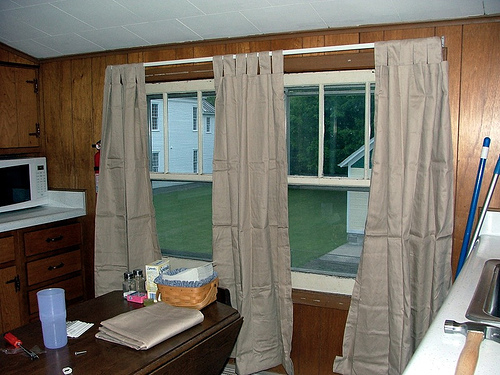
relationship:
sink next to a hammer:
[466, 258, 499, 322] [444, 319, 499, 373]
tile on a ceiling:
[54, 5, 108, 39] [37, 0, 90, 31]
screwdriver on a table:
[2, 330, 41, 360] [2, 278, 253, 373]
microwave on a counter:
[1, 155, 48, 219] [0, 190, 85, 238]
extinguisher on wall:
[91, 137, 107, 193] [39, 16, 499, 373]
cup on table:
[34, 285, 73, 348] [8, 287, 237, 374]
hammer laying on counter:
[445, 304, 492, 371] [402, 208, 499, 372]